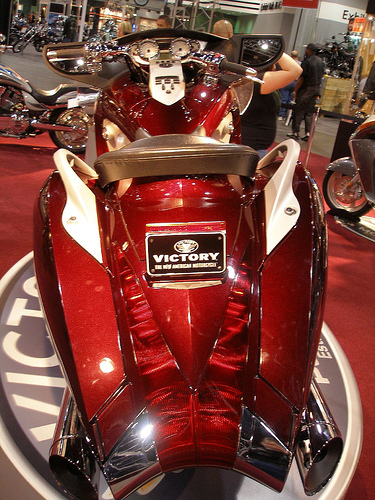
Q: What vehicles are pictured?
A: Motorcycles.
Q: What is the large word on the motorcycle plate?
A: Victory.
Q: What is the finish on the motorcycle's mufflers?
A: Chrome.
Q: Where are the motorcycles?
A: In a showroom.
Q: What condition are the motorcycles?
A: New.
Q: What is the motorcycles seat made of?
A: Leather.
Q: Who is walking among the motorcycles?
A: Shoppers.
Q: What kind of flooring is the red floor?
A: Carpet.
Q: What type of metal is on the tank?
A: Chrome.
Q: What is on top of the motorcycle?
A: Seat.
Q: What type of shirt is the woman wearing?
A: Black t shirt.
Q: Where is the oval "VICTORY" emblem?
A: On the floor.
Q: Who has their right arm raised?
A: The person in black.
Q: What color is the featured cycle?
A: Red.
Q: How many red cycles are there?
A: 1.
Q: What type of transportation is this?
A: Motorcycle.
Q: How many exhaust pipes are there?
A: 2.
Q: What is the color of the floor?
A: Red.